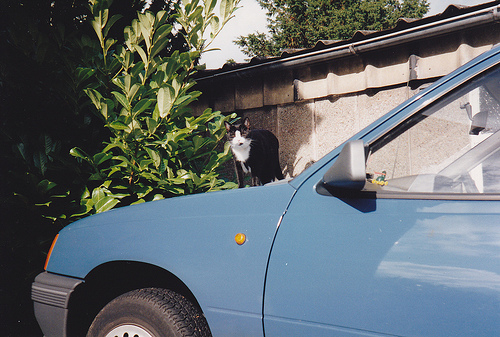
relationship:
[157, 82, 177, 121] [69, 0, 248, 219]
leaf on tree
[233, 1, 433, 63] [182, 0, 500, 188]
tree behind structure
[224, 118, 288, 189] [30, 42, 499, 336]
cat on car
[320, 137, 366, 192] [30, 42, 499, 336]
mirror on car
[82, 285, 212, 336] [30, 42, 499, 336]
tire on car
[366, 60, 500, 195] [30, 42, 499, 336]
window on car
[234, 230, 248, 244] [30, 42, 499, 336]
reflector on car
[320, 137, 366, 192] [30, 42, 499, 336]
rearview mirror on car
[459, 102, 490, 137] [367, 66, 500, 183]
rearview mirror on windshield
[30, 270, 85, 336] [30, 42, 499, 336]
bumper on car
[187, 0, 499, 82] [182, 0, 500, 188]
roof on structure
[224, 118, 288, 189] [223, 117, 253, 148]
cat has head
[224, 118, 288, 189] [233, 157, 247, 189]
cat has leg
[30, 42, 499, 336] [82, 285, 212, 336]
car has front wheel